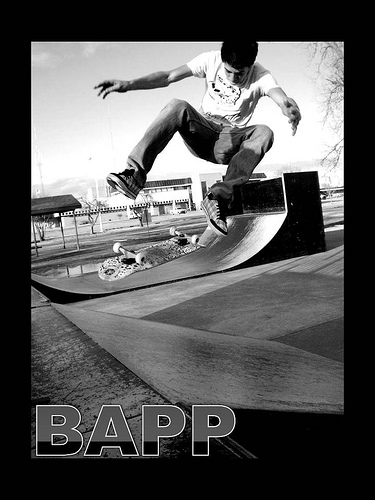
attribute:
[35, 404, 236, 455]
decoration — text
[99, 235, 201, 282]
deck — painted, skateboard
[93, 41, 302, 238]
man — young, jumping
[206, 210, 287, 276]
ramp — skateboard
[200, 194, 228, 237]
shoe — checkered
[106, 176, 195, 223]
building — large, public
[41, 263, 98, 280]
water — muddy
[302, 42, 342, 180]
tree — leafless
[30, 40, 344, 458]
picture — black, white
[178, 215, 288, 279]
ramp — skateboard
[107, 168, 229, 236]
sneakers — striped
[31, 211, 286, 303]
ramp — skateboard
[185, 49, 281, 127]
t-shirt — white